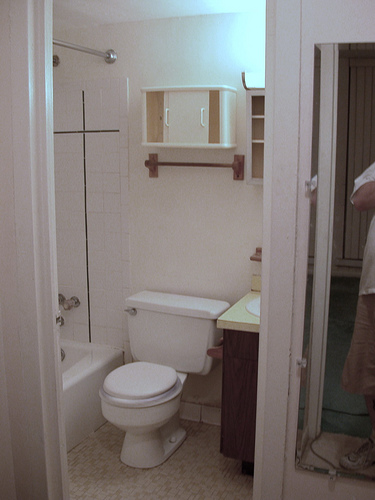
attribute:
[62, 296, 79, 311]
knob — shower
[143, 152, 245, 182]
rack — wooden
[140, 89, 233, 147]
cabinet — white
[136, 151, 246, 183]
bar — long, wooden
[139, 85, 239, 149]
cabinets — white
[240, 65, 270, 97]
portion — Lit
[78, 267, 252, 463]
toilet — porcelain, white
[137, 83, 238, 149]
cabinet — white, brown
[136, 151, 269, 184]
handle — silver, toilet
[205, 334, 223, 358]
tissue holder — wooden